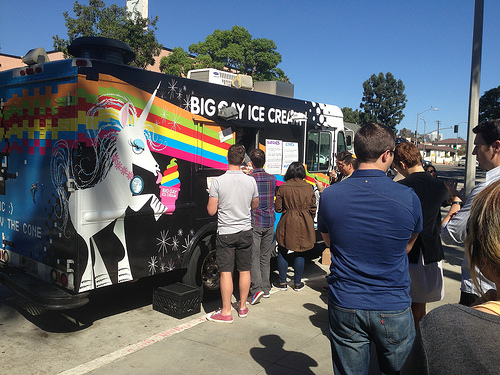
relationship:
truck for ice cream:
[5, 43, 344, 337] [251, 104, 303, 128]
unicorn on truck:
[62, 76, 165, 290] [5, 43, 344, 337]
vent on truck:
[69, 35, 140, 65] [5, 43, 344, 337]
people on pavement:
[207, 144, 259, 324] [6, 277, 333, 371]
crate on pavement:
[150, 282, 207, 321] [6, 277, 333, 371]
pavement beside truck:
[6, 277, 333, 371] [5, 43, 344, 337]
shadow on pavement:
[248, 301, 334, 372] [6, 277, 333, 371]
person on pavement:
[278, 163, 314, 286] [6, 277, 333, 371]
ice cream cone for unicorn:
[157, 159, 184, 211] [62, 76, 165, 290]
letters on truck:
[187, 92, 308, 130] [5, 43, 344, 337]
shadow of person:
[248, 301, 334, 372] [320, 125, 422, 370]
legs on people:
[223, 269, 251, 311] [207, 144, 259, 324]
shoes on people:
[210, 307, 257, 326] [207, 144, 259, 324]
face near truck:
[329, 151, 358, 177] [5, 43, 344, 337]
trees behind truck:
[50, 5, 281, 80] [5, 43, 344, 337]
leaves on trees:
[205, 42, 254, 59] [50, 5, 281, 80]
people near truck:
[214, 82, 500, 369] [5, 43, 344, 337]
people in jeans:
[207, 144, 259, 324] [321, 301, 419, 372]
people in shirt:
[207, 144, 259, 324] [318, 175, 420, 311]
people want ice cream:
[214, 82, 500, 369] [251, 104, 303, 128]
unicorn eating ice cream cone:
[62, 76, 165, 290] [157, 159, 184, 211]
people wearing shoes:
[207, 144, 259, 324] [210, 307, 257, 326]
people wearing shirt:
[207, 144, 259, 324] [318, 175, 420, 311]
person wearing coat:
[278, 163, 314, 286] [275, 178, 317, 249]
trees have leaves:
[50, 5, 281, 80] [205, 42, 254, 59]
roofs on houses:
[410, 134, 464, 154] [404, 130, 475, 166]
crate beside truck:
[150, 282, 207, 321] [5, 43, 344, 337]